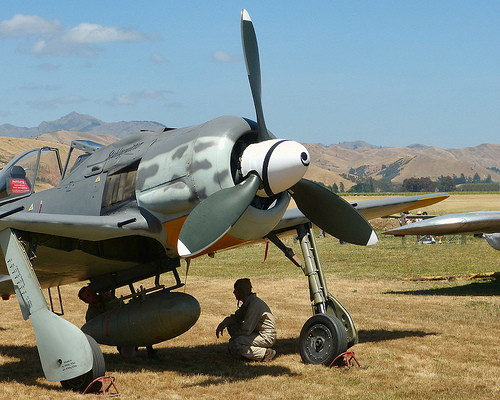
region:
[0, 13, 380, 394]
THIS IS A PLANE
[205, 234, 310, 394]
this is a person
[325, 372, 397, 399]
a patch of grass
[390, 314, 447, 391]
a patch of grass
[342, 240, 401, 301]
a patch of grass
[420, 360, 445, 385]
a patch of grass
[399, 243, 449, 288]
a patch of grass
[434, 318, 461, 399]
a patch of grass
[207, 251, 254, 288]
a patch of grass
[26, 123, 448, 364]
this is in a field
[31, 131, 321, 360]
this a fighter plane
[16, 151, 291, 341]
this plane is very old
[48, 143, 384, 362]
the fighter plane is gray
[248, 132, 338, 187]
the propellor is white and black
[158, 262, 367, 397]
the made is under the plane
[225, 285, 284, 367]
the man has a flight suit on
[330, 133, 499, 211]
there are mountains in the background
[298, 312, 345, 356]
the wheel is black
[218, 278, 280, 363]
a man onthe ground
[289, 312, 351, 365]
a air plane wheel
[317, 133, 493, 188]
brown mountains in the back ground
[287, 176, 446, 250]
the left wing of a plane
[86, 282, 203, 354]
a silver bomb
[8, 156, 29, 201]
a head rest in the cockpit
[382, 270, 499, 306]
a shadow of a plane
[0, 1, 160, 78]
a fluffy white cloud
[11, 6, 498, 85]
a blue and white sky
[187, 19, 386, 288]
propeller or plane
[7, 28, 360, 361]
gray old plane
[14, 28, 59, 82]
white clouds in blue sky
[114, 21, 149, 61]
white clouds in blue sky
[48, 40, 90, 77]
white clouds in blue sky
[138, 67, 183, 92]
white clouds in blue sky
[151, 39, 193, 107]
white clouds in blue sky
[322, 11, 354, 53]
white clouds in blue sky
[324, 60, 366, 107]
white clouds in blue sky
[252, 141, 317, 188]
white nose of plane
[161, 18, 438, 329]
the propeller is black and white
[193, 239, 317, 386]
man sitting under the jet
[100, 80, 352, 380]
man sitting under the jet